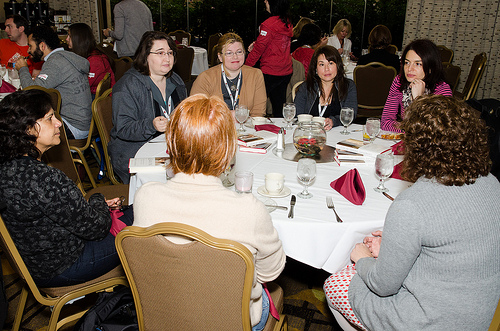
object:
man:
[12, 25, 93, 147]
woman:
[380, 37, 454, 134]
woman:
[294, 44, 358, 133]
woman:
[188, 32, 268, 117]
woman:
[107, 30, 188, 184]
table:
[127, 117, 462, 276]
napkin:
[330, 168, 367, 206]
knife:
[288, 195, 297, 219]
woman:
[322, 94, 499, 331]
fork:
[326, 194, 344, 224]